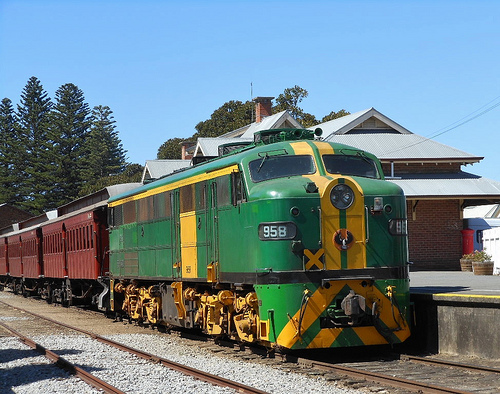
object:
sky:
[159, 1, 335, 72]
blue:
[400, 7, 489, 84]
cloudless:
[15, 5, 82, 52]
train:
[0, 135, 415, 353]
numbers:
[277, 225, 288, 239]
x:
[301, 249, 326, 270]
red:
[43, 227, 55, 230]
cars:
[41, 221, 66, 278]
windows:
[248, 154, 313, 182]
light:
[328, 182, 355, 210]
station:
[409, 171, 500, 322]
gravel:
[125, 366, 159, 389]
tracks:
[464, 384, 500, 393]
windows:
[90, 224, 95, 249]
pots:
[460, 259, 472, 273]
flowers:
[471, 253, 475, 256]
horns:
[310, 127, 324, 137]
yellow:
[324, 210, 338, 229]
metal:
[183, 368, 197, 375]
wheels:
[62, 294, 75, 308]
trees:
[77, 105, 126, 183]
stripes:
[306, 327, 346, 348]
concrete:
[412, 272, 471, 283]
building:
[408, 203, 458, 270]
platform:
[468, 275, 497, 358]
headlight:
[288, 207, 301, 217]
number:
[394, 222, 407, 235]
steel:
[90, 378, 114, 390]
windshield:
[251, 159, 314, 178]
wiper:
[257, 154, 267, 171]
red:
[426, 210, 441, 224]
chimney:
[252, 96, 275, 122]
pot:
[474, 262, 495, 276]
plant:
[472, 251, 491, 259]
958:
[262, 224, 288, 238]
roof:
[405, 147, 458, 198]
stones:
[132, 353, 137, 357]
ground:
[202, 352, 227, 373]